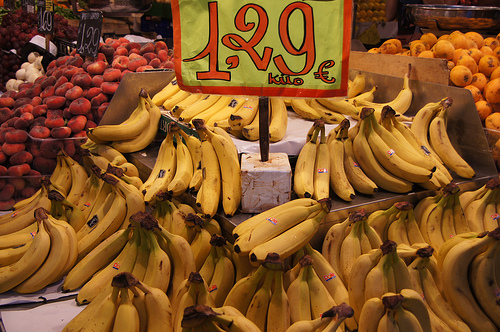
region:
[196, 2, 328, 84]
yellow sign with oranges numbers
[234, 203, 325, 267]
a bunch of bananas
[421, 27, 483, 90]
oranges in a bin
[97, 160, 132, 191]
stems of some bananas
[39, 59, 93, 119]
fruit in a pile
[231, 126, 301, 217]
a block holding a sign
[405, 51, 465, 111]
a brown divider between fruit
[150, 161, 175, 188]
a black spot on a banana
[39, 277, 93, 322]
white table covering for bananas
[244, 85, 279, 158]
pole holding a sign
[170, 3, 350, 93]
Price sign for bananas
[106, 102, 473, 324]
Bunches of bananas for sale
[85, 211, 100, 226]
A sticker on a banana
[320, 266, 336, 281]
Dole sticker on a banana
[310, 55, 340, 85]
Euro symbol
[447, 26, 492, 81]
What might be oranges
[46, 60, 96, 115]
exotic fruit that looks like squashed peaches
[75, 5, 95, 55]
Price sign for the fruit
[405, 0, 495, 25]
Silver bowl of a scale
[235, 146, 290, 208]
A cube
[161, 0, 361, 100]
yellow and orange sign advertising the price of the bananas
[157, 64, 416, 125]
bananas sitting on the top row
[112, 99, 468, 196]
bananas sitting on the middle row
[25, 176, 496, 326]
bananas sitting on the bottom row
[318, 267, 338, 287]
sticker of the brand of banana on top of a bunch of bananas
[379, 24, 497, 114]
orange colored fruit sitting to the right of the banana display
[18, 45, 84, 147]
reddish orange color of fruit sitting to the left of the banana display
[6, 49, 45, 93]
onions sitting to the left of the reddish orange display of fruit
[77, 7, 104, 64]
black board with chalk writing displaying the price of the reddish orange fruit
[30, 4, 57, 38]
black board with chalk writing telling the price of the onions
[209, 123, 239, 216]
a ripe banana on display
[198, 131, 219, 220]
a ripe banana on display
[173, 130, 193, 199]
a ripe banana on display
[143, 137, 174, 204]
a ripe banana on display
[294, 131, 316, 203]
a ripe banana on display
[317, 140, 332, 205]
a ripe banana on display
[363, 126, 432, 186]
a ripe banana on display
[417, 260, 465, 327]
a ripe banana on display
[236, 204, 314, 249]
a ripe banana on display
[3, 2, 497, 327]
fruits on display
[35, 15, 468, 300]
Picture is taken outside.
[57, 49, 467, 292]
Picture has a variety of fruit shown.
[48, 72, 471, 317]
Many bananas are on the table.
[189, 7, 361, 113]
The sign is orange and yellow.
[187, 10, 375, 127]
The sign says 1.29 kilo.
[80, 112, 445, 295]
The bananas are yellow.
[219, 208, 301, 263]
Stickers are on the bananas.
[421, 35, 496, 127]
These fruits are orange in color.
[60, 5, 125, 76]
The sign is black and white in color.